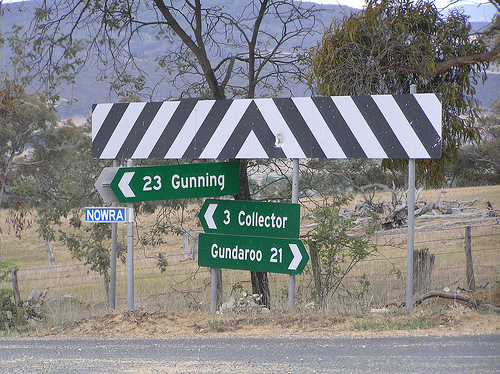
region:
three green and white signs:
[93, 162, 330, 279]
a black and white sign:
[94, 90, 439, 165]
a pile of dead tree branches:
[312, 173, 494, 231]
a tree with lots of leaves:
[311, 18, 488, 209]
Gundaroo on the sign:
[208, 238, 265, 270]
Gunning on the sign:
[168, 168, 230, 206]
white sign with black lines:
[86, 95, 466, 160]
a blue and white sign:
[86, 203, 140, 230]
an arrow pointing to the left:
[281, 241, 306, 272]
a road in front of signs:
[1, 323, 490, 373]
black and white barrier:
[92, 94, 442, 155]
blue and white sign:
[85, 207, 125, 224]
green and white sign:
[201, 200, 298, 236]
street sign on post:
[198, 232, 309, 276]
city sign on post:
[108, 160, 241, 200]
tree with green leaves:
[298, 0, 488, 195]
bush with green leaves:
[303, 200, 375, 302]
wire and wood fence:
[310, 225, 499, 315]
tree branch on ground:
[386, 289, 482, 307]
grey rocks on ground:
[218, 291, 265, 315]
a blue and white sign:
[78, 194, 131, 226]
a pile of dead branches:
[330, 173, 485, 246]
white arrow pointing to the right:
[284, 240, 320, 277]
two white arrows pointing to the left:
[118, 170, 219, 234]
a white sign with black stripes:
[94, 88, 451, 165]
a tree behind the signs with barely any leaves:
[0, 1, 282, 315]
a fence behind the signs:
[27, 221, 497, 326]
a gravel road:
[8, 334, 493, 369]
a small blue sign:
[82, 200, 134, 226]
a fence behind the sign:
[22, 223, 494, 326]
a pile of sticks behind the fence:
[302, 177, 484, 239]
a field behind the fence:
[0, 181, 495, 300]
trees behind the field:
[5, 8, 497, 210]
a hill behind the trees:
[0, 4, 499, 106]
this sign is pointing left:
[194, 195, 300, 244]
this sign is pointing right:
[192, 229, 307, 276]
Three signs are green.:
[112, 154, 337, 277]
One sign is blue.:
[79, 198, 141, 236]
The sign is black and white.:
[77, 76, 455, 167]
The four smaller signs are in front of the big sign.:
[79, 165, 320, 268]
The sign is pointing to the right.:
[195, 231, 320, 280]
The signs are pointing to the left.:
[122, 166, 308, 231]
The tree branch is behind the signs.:
[317, 187, 496, 234]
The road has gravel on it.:
[9, 318, 234, 367]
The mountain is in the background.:
[3, 1, 397, 98]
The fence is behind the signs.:
[3, 239, 192, 344]